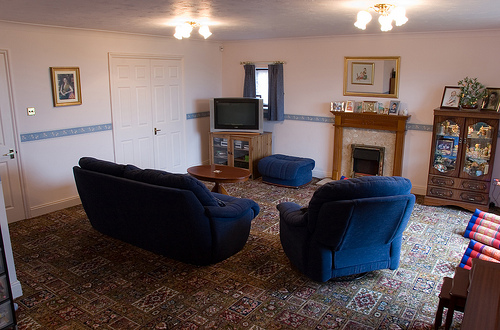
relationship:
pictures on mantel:
[327, 98, 411, 119] [327, 115, 414, 131]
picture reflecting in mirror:
[347, 61, 375, 83] [339, 51, 402, 100]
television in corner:
[208, 97, 259, 128] [195, 44, 288, 174]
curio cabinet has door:
[422, 106, 500, 213] [429, 121, 492, 174]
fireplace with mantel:
[332, 106, 409, 173] [327, 115, 414, 131]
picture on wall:
[347, 61, 375, 83] [48, 66, 88, 107]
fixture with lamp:
[156, 0, 220, 49] [198, 23, 211, 40]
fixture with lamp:
[156, 0, 220, 49] [170, 17, 190, 41]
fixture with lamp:
[162, 0, 220, 40] [201, 25, 212, 41]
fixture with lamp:
[342, 0, 412, 35] [170, 17, 190, 41]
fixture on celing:
[156, 0, 220, 49] [46, 15, 325, 31]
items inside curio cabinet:
[429, 121, 492, 174] [410, 81, 500, 213]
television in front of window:
[209, 97, 265, 134] [252, 66, 275, 110]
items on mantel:
[332, 96, 408, 118] [329, 110, 411, 132]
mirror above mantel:
[339, 51, 402, 100] [329, 110, 411, 132]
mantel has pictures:
[327, 115, 414, 131] [327, 98, 411, 119]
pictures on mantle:
[327, 98, 411, 119] [327, 101, 406, 127]